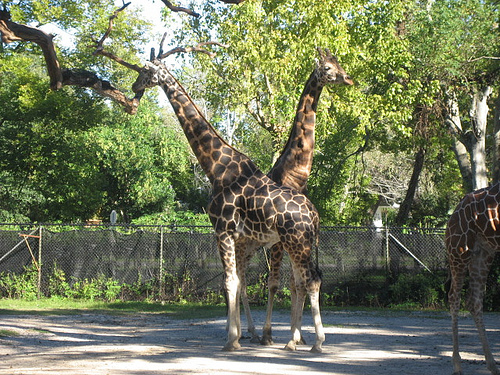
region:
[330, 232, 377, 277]
grey metal chain fencing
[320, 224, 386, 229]
grey metal fencing support post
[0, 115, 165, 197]
large green tree with leaves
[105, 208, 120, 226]
silver back of street sign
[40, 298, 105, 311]
grass growing on ground beside fence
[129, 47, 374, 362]
two giraffes standing in sun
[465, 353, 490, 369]
giraffe droppings on ground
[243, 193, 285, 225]
pattern on side of giraffe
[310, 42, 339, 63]
brown horns on giraffe head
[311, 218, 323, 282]
black and orange giraffe tail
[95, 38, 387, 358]
Two giraffes are together.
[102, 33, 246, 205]
The giraffe faces left.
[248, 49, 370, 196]
The giraffe faces right.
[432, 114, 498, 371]
A third giraffe is off to the side.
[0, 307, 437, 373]
Sunlight shines on the ground.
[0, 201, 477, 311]
A fence is behind the giraffes.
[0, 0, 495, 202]
Trees are behind the fence.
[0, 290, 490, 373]
The ground is made of dirt.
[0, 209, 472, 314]
The fence is made of metal.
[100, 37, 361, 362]
The giraffe is the same height as the branch.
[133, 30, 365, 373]
two giraffes facing opposite directions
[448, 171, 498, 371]
backside of one giraffe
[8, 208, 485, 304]
chain link fence covered in black tarp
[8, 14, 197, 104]
large tree branch in corner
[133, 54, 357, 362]
two giraffes with black spots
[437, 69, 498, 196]
two tree trunks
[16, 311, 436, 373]
black pavement with sun shining on it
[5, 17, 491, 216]
trees with green leaves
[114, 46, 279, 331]
giraffe facing to the left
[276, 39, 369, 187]
giraffe facing to the right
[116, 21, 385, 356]
Two giraffes standing together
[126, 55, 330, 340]
giraffe is dark brown and white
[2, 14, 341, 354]
Giraffe touching tree branch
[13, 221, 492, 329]
Chain link fence behind giraffes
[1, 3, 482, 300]
Trees behind chain fence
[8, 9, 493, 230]
trees have lots of leaves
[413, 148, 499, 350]
Rear end of third giraffe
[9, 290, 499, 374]
shadows are on the ground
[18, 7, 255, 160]
The sky is clear and blue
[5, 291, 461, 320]
a little bit of grass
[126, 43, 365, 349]
two zebras facing opposite direction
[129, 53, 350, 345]
zebras with dark brown spots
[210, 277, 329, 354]
zebras with white legs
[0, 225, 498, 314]
chain-link fence behind zebras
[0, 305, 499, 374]
shadows with zebras and trees on ground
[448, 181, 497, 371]
partial view of another zebra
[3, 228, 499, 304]
extra covering behind chain-link fence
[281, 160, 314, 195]
horizontal lines under zebra's neck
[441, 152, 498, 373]
zebra's head cut off in photo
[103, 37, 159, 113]
zebra eating off a tree branch